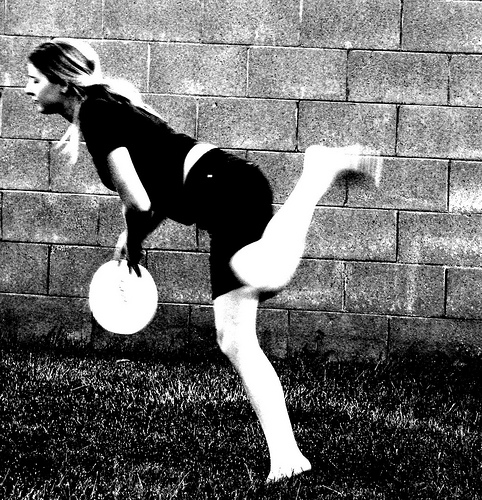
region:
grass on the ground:
[33, 386, 199, 457]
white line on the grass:
[33, 354, 209, 422]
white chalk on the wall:
[166, 25, 380, 106]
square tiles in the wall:
[165, 23, 405, 100]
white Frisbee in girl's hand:
[73, 240, 156, 330]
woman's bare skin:
[177, 138, 243, 162]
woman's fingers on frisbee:
[104, 244, 174, 288]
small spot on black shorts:
[191, 170, 237, 202]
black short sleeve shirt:
[62, 98, 207, 221]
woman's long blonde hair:
[19, 28, 168, 156]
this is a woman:
[45, 29, 362, 460]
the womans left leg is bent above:
[229, 133, 386, 303]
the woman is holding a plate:
[91, 241, 156, 333]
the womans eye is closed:
[32, 75, 40, 85]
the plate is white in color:
[92, 263, 153, 331]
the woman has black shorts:
[204, 168, 259, 239]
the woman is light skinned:
[278, 221, 293, 253]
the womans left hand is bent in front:
[108, 139, 159, 235]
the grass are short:
[0, 387, 230, 498]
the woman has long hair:
[93, 80, 121, 96]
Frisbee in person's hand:
[29, 222, 109, 299]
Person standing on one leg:
[210, 272, 331, 422]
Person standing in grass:
[119, 341, 353, 487]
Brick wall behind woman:
[309, 221, 437, 338]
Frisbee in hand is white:
[52, 225, 180, 396]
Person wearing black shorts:
[202, 146, 268, 294]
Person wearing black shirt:
[37, 104, 151, 210]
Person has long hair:
[12, 42, 137, 178]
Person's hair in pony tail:
[31, 39, 159, 190]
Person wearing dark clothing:
[78, 101, 273, 360]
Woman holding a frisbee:
[85, 257, 166, 340]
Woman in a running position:
[14, 38, 389, 482]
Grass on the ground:
[1, 341, 205, 499]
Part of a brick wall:
[339, 0, 481, 316]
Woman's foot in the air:
[297, 135, 389, 196]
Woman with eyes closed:
[18, 40, 108, 120]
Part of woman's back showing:
[175, 137, 217, 190]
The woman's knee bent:
[227, 239, 324, 300]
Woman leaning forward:
[12, 38, 272, 227]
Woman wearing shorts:
[181, 148, 277, 300]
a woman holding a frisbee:
[11, 33, 425, 329]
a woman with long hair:
[14, 37, 136, 151]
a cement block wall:
[205, 15, 453, 127]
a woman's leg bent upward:
[213, 138, 391, 310]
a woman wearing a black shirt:
[23, 53, 186, 194]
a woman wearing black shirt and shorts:
[18, 29, 427, 317]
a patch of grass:
[28, 354, 463, 494]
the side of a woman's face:
[8, 29, 94, 124]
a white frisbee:
[66, 262, 175, 337]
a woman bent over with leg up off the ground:
[11, 32, 461, 481]